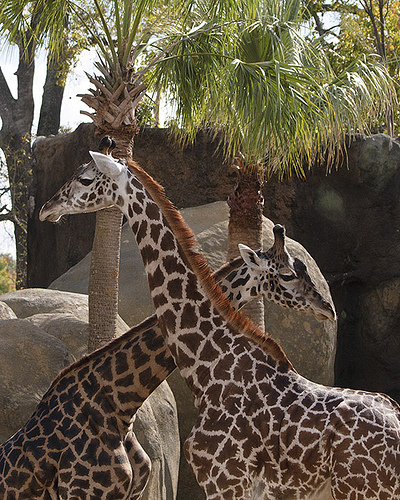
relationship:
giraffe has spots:
[38, 136, 399, 497] [167, 273, 202, 333]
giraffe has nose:
[38, 136, 399, 497] [36, 196, 59, 220]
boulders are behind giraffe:
[27, 119, 397, 394] [38, 136, 399, 497]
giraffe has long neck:
[38, 136, 399, 497] [119, 156, 231, 387]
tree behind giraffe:
[144, 12, 384, 330] [38, 136, 399, 497]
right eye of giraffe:
[278, 267, 299, 288] [2, 219, 338, 493]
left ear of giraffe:
[87, 149, 123, 178] [38, 136, 399, 497]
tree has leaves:
[144, 12, 384, 330] [278, 51, 396, 171]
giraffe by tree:
[38, 136, 399, 497] [144, 12, 384, 330]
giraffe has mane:
[38, 136, 399, 497] [122, 154, 297, 375]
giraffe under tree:
[38, 136, 399, 497] [144, 12, 384, 330]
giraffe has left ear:
[38, 136, 399, 497] [87, 149, 123, 178]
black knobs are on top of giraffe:
[95, 135, 118, 156] [38, 136, 399, 497]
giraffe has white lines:
[38, 136, 399, 497] [270, 399, 382, 459]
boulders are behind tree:
[27, 119, 397, 394] [144, 12, 384, 330]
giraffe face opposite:
[0, 223, 337, 500] [36, 132, 341, 333]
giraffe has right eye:
[2, 219, 338, 493] [278, 267, 299, 288]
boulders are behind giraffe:
[27, 119, 397, 394] [0, 223, 337, 500]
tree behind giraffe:
[144, 12, 384, 330] [0, 223, 337, 500]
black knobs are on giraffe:
[95, 135, 118, 156] [38, 136, 399, 497]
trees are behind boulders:
[295, 6, 397, 138] [27, 119, 397, 394]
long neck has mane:
[119, 156, 231, 387] [122, 154, 297, 375]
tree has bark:
[144, 12, 384, 330] [216, 155, 264, 259]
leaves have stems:
[278, 51, 396, 171] [299, 58, 370, 116]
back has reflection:
[291, 372, 396, 429] [288, 368, 400, 427]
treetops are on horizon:
[128, 96, 192, 130] [10, 86, 398, 139]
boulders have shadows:
[27, 119, 397, 394] [36, 121, 390, 179]